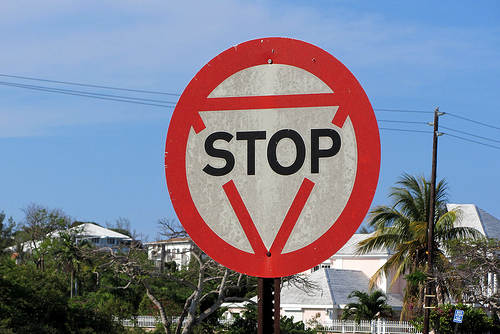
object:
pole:
[418, 107, 444, 334]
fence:
[305, 317, 420, 334]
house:
[219, 203, 500, 334]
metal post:
[255, 276, 283, 334]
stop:
[201, 128, 340, 177]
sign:
[452, 309, 464, 323]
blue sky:
[0, 0, 500, 221]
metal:
[256, 278, 281, 334]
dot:
[272, 291, 276, 295]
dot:
[271, 299, 275, 304]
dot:
[271, 308, 275, 313]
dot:
[271, 316, 275, 321]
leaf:
[385, 187, 420, 220]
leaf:
[363, 204, 411, 233]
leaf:
[346, 234, 409, 260]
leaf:
[436, 225, 485, 249]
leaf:
[432, 174, 453, 224]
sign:
[164, 36, 382, 279]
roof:
[43, 221, 131, 240]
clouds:
[0, 0, 500, 134]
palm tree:
[349, 170, 487, 333]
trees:
[0, 201, 324, 333]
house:
[0, 222, 194, 286]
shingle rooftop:
[220, 268, 402, 309]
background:
[0, 0, 500, 334]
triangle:
[183, 93, 357, 257]